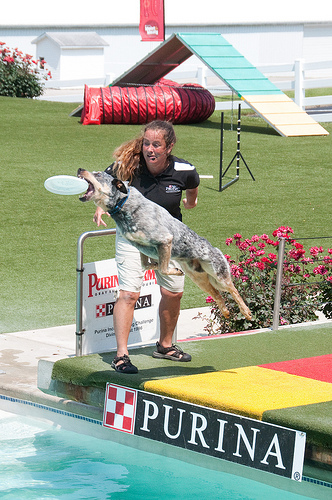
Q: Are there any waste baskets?
A: No, there are no waste baskets.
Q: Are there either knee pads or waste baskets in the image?
A: No, there are no waste baskets or knee pads.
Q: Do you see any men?
A: No, there are no men.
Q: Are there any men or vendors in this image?
A: No, there are no men or vendors.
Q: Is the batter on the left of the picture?
A: Yes, the batter is on the left of the image.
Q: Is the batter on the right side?
A: No, the batter is on the left of the image.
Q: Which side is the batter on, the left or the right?
A: The batter is on the left of the image.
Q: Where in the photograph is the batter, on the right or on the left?
A: The batter is on the left of the image.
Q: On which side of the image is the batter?
A: The batter is on the left of the image.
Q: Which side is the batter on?
A: The batter is on the left of the image.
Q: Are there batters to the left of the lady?
A: Yes, there is a batter to the left of the lady.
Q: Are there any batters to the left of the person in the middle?
A: Yes, there is a batter to the left of the lady.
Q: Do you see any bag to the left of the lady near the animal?
A: No, there is a batter to the left of the lady.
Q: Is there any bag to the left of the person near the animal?
A: No, there is a batter to the left of the lady.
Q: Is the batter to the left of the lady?
A: Yes, the batter is to the left of the lady.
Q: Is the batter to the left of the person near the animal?
A: Yes, the batter is to the left of the lady.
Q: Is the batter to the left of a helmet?
A: No, the batter is to the left of the lady.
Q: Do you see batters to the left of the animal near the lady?
A: Yes, there is a batter to the left of the animal.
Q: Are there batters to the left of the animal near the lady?
A: Yes, there is a batter to the left of the animal.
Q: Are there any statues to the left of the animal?
A: No, there is a batter to the left of the animal.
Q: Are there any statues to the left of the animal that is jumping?
A: No, there is a batter to the left of the animal.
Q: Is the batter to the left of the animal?
A: Yes, the batter is to the left of the animal.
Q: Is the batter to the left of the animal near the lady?
A: Yes, the batter is to the left of the animal.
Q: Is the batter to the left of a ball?
A: No, the batter is to the left of the animal.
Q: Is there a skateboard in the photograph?
A: No, there are no skateboards.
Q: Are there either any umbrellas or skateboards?
A: No, there are no skateboards or umbrellas.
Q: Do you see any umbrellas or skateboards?
A: No, there are no skateboards or umbrellas.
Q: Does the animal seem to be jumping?
A: Yes, the animal is jumping.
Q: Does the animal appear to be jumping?
A: Yes, the animal is jumping.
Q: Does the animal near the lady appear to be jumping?
A: Yes, the animal is jumping.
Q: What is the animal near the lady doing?
A: The animal is jumping.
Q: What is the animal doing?
A: The animal is jumping.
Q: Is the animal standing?
A: No, the animal is jumping.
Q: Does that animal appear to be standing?
A: No, the animal is jumping.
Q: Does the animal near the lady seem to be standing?
A: No, the animal is jumping.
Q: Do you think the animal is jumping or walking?
A: The animal is jumping.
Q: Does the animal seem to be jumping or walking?
A: The animal is jumping.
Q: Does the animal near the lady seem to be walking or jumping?
A: The animal is jumping.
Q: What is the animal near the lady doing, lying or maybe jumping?
A: The animal is jumping.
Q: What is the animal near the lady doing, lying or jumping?
A: The animal is jumping.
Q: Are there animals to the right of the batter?
A: Yes, there is an animal to the right of the batter.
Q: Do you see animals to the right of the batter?
A: Yes, there is an animal to the right of the batter.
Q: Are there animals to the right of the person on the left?
A: Yes, there is an animal to the right of the batter.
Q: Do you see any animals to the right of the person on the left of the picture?
A: Yes, there is an animal to the right of the batter.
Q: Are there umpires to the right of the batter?
A: No, there is an animal to the right of the batter.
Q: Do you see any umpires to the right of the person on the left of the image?
A: No, there is an animal to the right of the batter.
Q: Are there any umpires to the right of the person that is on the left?
A: No, there is an animal to the right of the batter.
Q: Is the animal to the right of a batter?
A: Yes, the animal is to the right of a batter.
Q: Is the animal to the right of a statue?
A: No, the animal is to the right of a batter.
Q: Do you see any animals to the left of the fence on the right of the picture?
A: Yes, there is an animal to the left of the fence.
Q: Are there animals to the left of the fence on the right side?
A: Yes, there is an animal to the left of the fence.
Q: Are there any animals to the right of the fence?
A: No, the animal is to the left of the fence.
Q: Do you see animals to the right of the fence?
A: No, the animal is to the left of the fence.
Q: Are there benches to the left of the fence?
A: No, there is an animal to the left of the fence.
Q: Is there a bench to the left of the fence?
A: No, there is an animal to the left of the fence.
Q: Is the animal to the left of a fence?
A: Yes, the animal is to the left of a fence.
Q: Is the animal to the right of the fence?
A: No, the animal is to the left of the fence.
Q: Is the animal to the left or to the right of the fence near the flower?
A: The animal is to the left of the fence.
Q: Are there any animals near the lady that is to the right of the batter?
A: Yes, there is an animal near the lady.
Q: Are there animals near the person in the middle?
A: Yes, there is an animal near the lady.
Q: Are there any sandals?
A: Yes, there are sandals.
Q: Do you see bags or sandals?
A: Yes, there are sandals.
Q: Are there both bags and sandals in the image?
A: No, there are sandals but no bags.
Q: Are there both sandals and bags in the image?
A: No, there are sandals but no bags.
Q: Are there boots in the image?
A: No, there are no boots.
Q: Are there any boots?
A: No, there are no boots.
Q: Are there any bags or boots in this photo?
A: No, there are no boots or bags.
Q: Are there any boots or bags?
A: No, there are no boots or bags.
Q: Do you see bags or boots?
A: No, there are no boots or bags.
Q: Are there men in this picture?
A: No, there are no men.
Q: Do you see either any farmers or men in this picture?
A: No, there are no men or farmers.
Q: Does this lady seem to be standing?
A: Yes, the lady is standing.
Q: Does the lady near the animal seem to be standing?
A: Yes, the lady is standing.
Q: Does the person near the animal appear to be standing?
A: Yes, the lady is standing.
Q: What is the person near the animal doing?
A: The lady is standing.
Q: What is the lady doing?
A: The lady is standing.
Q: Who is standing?
A: The lady is standing.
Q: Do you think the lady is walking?
A: No, the lady is standing.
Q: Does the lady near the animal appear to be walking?
A: No, the lady is standing.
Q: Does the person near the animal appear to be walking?
A: No, the lady is standing.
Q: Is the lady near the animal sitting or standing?
A: The lady is standing.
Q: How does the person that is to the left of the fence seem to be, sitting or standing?
A: The lady is standing.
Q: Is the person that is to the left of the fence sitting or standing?
A: The lady is standing.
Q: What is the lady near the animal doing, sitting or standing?
A: The lady is standing.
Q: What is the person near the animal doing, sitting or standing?
A: The lady is standing.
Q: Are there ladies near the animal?
A: Yes, there is a lady near the animal.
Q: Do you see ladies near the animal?
A: Yes, there is a lady near the animal.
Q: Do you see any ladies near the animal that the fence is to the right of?
A: Yes, there is a lady near the animal.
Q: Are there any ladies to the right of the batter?
A: Yes, there is a lady to the right of the batter.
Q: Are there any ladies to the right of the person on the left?
A: Yes, there is a lady to the right of the batter.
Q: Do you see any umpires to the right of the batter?
A: No, there is a lady to the right of the batter.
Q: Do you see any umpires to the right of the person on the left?
A: No, there is a lady to the right of the batter.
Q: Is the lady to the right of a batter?
A: Yes, the lady is to the right of a batter.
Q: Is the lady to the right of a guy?
A: No, the lady is to the right of a batter.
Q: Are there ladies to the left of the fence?
A: Yes, there is a lady to the left of the fence.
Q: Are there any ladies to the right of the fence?
A: No, the lady is to the left of the fence.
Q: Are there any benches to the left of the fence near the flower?
A: No, there is a lady to the left of the fence.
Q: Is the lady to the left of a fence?
A: Yes, the lady is to the left of a fence.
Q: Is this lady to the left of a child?
A: No, the lady is to the left of a fence.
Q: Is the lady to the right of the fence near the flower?
A: No, the lady is to the left of the fence.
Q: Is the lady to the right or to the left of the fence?
A: The lady is to the left of the fence.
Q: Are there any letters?
A: Yes, there are letters.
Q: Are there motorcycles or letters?
A: Yes, there are letters.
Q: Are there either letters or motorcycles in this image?
A: Yes, there are letters.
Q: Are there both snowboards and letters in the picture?
A: No, there are letters but no snowboards.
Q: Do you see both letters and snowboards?
A: No, there are letters but no snowboards.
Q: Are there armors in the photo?
A: No, there are no armors.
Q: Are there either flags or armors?
A: No, there are no armors or flags.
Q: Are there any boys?
A: No, there are no boys.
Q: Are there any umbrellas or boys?
A: No, there are no boys or umbrellas.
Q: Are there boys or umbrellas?
A: No, there are no boys or umbrellas.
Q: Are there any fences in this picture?
A: Yes, there is a fence.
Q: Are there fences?
A: Yes, there is a fence.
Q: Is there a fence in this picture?
A: Yes, there is a fence.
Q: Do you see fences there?
A: Yes, there is a fence.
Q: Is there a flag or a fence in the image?
A: Yes, there is a fence.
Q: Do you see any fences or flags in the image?
A: Yes, there is a fence.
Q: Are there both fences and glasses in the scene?
A: No, there is a fence but no glasses.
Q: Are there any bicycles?
A: No, there are no bicycles.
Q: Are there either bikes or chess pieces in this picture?
A: No, there are no bikes or chess pieces.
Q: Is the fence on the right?
A: Yes, the fence is on the right of the image.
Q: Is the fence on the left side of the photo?
A: No, the fence is on the right of the image.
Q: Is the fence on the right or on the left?
A: The fence is on the right of the image.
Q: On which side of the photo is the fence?
A: The fence is on the right of the image.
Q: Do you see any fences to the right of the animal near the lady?
A: Yes, there is a fence to the right of the animal.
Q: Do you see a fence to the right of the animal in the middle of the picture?
A: Yes, there is a fence to the right of the animal.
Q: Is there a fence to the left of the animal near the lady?
A: No, the fence is to the right of the animal.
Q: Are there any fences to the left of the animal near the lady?
A: No, the fence is to the right of the animal.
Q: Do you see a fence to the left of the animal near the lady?
A: No, the fence is to the right of the animal.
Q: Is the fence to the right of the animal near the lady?
A: Yes, the fence is to the right of the animal.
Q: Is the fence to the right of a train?
A: No, the fence is to the right of the animal.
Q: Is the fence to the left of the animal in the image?
A: No, the fence is to the right of the animal.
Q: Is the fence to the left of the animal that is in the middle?
A: No, the fence is to the right of the animal.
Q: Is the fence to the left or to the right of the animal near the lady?
A: The fence is to the right of the animal.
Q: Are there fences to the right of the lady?
A: Yes, there is a fence to the right of the lady.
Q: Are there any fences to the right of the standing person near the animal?
A: Yes, there is a fence to the right of the lady.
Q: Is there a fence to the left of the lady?
A: No, the fence is to the right of the lady.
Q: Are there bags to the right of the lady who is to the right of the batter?
A: No, there is a fence to the right of the lady.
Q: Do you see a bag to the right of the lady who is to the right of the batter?
A: No, there is a fence to the right of the lady.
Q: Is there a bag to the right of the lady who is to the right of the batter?
A: No, there is a fence to the right of the lady.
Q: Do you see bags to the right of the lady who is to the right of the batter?
A: No, there is a fence to the right of the lady.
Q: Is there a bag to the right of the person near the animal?
A: No, there is a fence to the right of the lady.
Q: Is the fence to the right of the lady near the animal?
A: Yes, the fence is to the right of the lady.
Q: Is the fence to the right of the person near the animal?
A: Yes, the fence is to the right of the lady.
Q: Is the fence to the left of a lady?
A: No, the fence is to the right of a lady.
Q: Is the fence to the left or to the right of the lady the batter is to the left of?
A: The fence is to the right of the lady.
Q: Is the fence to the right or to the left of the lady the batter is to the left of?
A: The fence is to the right of the lady.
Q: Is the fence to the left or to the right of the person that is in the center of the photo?
A: The fence is to the right of the lady.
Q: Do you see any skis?
A: No, there are no skis.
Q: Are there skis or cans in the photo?
A: No, there are no skis or cans.